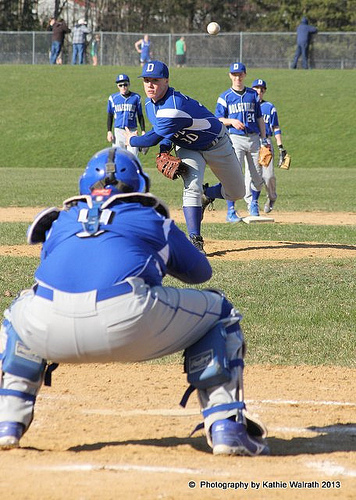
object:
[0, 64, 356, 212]
grass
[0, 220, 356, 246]
grass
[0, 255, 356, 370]
grass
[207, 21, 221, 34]
baseball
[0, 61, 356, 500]
baseball field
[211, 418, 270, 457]
shoe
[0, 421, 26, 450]
shoe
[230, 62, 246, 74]
cap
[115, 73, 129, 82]
cap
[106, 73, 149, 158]
player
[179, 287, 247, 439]
shin guard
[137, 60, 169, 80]
hat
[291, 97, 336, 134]
ground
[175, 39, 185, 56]
shirt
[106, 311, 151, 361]
back pocket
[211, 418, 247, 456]
heel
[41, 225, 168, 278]
strap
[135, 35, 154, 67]
person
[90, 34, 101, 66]
person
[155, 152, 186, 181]
glove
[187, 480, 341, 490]
copyright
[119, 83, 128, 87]
sunglasses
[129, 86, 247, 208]
uniform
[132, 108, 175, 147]
arm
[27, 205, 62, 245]
padding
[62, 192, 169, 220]
padding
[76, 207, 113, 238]
padding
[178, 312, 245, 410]
padding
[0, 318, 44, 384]
padding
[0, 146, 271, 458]
catcher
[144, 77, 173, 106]
shadow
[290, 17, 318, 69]
person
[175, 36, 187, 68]
person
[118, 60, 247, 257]
person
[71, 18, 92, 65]
person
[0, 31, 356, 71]
fence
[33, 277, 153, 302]
belt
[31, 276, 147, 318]
belt loops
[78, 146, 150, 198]
helmet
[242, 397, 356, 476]
outline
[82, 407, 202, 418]
home plate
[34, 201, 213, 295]
jersey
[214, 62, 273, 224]
baseball player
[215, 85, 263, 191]
uniform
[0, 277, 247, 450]
pants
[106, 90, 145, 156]
uniform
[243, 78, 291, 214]
player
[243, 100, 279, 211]
uniform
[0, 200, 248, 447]
uniform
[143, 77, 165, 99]
face